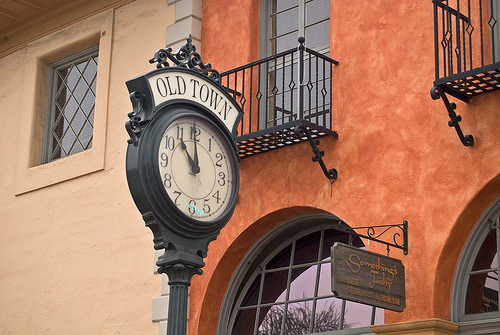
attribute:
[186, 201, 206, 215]
mark — spotted, blue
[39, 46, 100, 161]
blinds — closed, recessed, glass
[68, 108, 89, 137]
pane — diamond-shaped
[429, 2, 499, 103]
balcony — iron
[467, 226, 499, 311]
window — glass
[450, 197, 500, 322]
frame — green, painted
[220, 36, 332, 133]
fence — iron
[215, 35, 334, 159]
balcony — iron, black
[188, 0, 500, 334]
building — orange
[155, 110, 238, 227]
clock — white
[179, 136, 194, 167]
hand — black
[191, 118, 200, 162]
hand — black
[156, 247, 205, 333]
pole — metal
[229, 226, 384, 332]
window — glass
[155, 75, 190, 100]
word — old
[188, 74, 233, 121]
word — town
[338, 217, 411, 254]
brace — metal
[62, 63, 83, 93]
pane — diamond-shaped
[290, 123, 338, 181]
brace — black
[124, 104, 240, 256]
frame — black, metal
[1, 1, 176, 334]
wall — salmon-colored, tan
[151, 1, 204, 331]
row — vertical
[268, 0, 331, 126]
window — glass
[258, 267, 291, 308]
pane — square